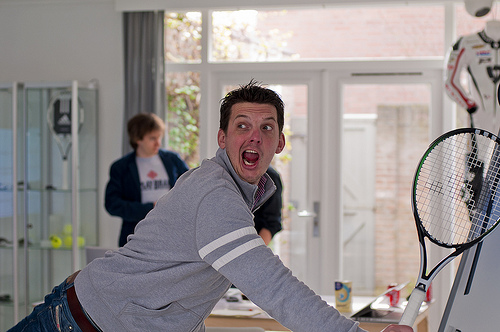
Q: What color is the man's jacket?
A: Grey.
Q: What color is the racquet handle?
A: White.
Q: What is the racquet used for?
A: Tennis.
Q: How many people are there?
A: 3.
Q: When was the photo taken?
A: Afternoon.